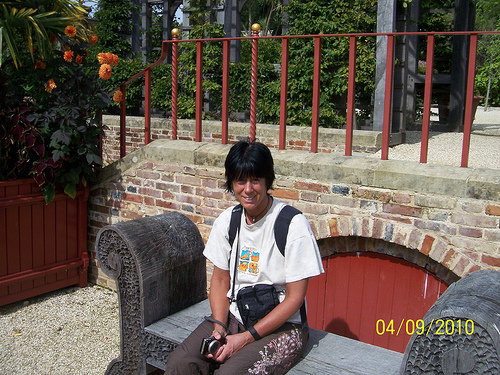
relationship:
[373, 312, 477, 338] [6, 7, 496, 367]
time stamp on video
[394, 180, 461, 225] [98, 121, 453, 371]
bricks on walls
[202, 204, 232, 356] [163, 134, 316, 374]
arm of a man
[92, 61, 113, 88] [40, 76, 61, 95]
flower next to flower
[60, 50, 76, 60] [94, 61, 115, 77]
flower next to flower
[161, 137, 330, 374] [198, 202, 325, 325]
lady wearing t shirt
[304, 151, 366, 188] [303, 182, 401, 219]
brick on wall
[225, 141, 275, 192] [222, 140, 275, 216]
hair on person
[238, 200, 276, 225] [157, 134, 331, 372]
necklace on lady